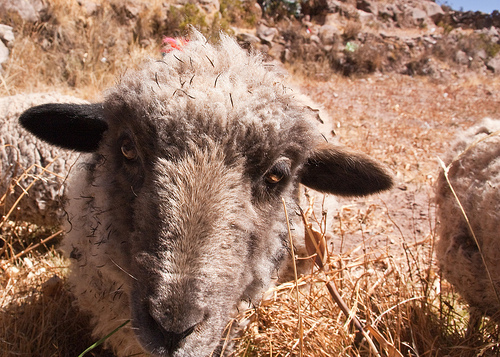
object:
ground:
[302, 75, 500, 270]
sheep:
[19, 22, 395, 356]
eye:
[261, 155, 292, 184]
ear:
[300, 145, 394, 196]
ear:
[17, 101, 106, 151]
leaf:
[302, 224, 327, 265]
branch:
[295, 203, 381, 356]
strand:
[205, 50, 218, 68]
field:
[2, 1, 500, 354]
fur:
[112, 22, 336, 140]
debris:
[153, 68, 161, 88]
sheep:
[0, 92, 90, 226]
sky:
[435, 1, 498, 12]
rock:
[7, 0, 50, 23]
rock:
[426, 1, 445, 25]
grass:
[233, 252, 499, 354]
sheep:
[431, 113, 500, 316]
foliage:
[344, 40, 354, 53]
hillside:
[1, 0, 500, 77]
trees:
[452, 11, 500, 28]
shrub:
[340, 54, 378, 76]